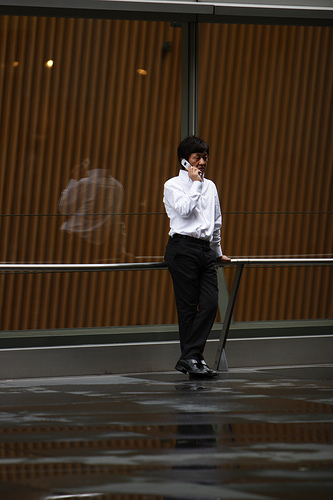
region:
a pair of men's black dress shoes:
[174, 356, 220, 377]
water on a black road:
[4, 404, 331, 495]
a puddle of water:
[222, 418, 281, 445]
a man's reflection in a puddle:
[166, 380, 222, 490]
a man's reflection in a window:
[57, 149, 129, 266]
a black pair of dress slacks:
[167, 235, 219, 362]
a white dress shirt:
[162, 169, 230, 258]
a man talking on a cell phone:
[160, 136, 241, 378]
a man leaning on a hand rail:
[160, 134, 234, 375]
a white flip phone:
[181, 159, 202, 178]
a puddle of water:
[41, 417, 171, 453]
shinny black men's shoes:
[175, 357, 219, 376]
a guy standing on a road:
[161, 137, 228, 379]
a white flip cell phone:
[178, 158, 199, 176]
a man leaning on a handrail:
[164, 134, 232, 377]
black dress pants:
[168, 236, 221, 359]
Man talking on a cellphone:
[157, 133, 231, 377]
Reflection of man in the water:
[167, 379, 235, 496]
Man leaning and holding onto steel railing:
[132, 252, 258, 271]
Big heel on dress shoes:
[172, 355, 192, 374]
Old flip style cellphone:
[180, 158, 207, 181]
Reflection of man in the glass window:
[47, 140, 151, 274]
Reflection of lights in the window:
[4, 55, 153, 84]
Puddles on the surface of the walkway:
[1, 376, 330, 498]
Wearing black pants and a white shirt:
[159, 168, 226, 361]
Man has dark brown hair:
[175, 134, 212, 172]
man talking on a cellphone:
[120, 129, 251, 338]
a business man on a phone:
[164, 137, 232, 339]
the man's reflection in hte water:
[166, 404, 225, 467]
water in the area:
[10, 391, 318, 487]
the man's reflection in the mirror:
[47, 141, 143, 266]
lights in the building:
[5, 47, 156, 80]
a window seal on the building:
[169, 20, 215, 232]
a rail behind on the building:
[6, 258, 331, 276]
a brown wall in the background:
[16, 24, 311, 218]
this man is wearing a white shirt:
[151, 164, 228, 240]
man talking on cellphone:
[167, 134, 232, 378]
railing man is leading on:
[0, 249, 330, 367]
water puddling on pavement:
[4, 377, 325, 499]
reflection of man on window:
[52, 147, 137, 259]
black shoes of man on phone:
[171, 352, 218, 380]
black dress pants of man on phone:
[160, 232, 217, 361]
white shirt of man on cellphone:
[169, 171, 223, 240]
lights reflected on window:
[7, 46, 153, 78]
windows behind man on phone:
[4, 14, 328, 340]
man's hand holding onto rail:
[215, 246, 232, 267]